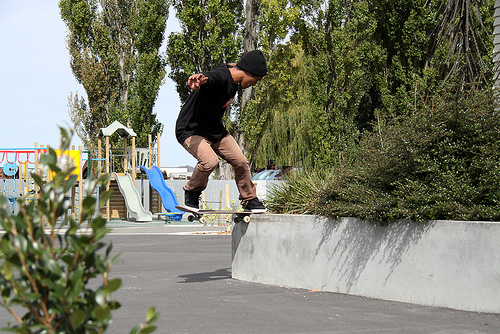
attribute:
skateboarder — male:
[175, 41, 271, 222]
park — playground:
[2, 125, 499, 333]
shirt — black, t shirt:
[171, 64, 241, 149]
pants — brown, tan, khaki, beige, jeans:
[172, 132, 262, 203]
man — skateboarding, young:
[173, 44, 271, 219]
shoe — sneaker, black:
[239, 195, 269, 218]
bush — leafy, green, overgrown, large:
[312, 92, 500, 229]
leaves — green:
[315, 90, 499, 231]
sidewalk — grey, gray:
[5, 233, 499, 334]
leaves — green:
[54, 0, 174, 149]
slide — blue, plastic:
[134, 163, 188, 226]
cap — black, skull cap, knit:
[233, 44, 273, 79]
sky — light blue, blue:
[2, 0, 352, 172]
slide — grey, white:
[106, 168, 157, 224]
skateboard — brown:
[168, 201, 265, 227]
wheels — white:
[184, 213, 254, 225]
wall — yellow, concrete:
[228, 211, 499, 314]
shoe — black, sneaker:
[180, 186, 205, 212]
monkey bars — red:
[0, 147, 50, 178]